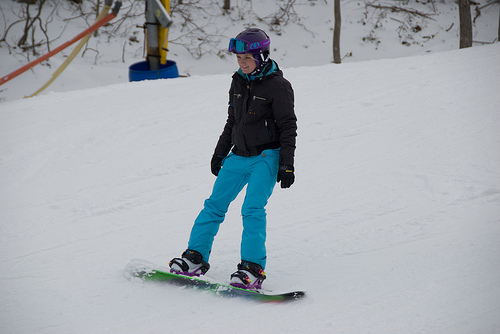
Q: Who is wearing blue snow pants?
A: A girl.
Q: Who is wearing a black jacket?
A: A girl.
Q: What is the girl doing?
A: Snowboarding.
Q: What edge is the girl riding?
A: Heelside.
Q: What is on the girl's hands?
A: Gloves.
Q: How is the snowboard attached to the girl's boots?
A: Bindings.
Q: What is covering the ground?
A: Snow.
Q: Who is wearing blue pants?
A: The girl.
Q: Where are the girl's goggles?
A: Around her helmet.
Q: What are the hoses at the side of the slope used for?
A: Snowmaking.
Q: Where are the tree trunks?
A: On the side of the slope.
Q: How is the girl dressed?
A: In heavy coat.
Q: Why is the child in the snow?
A: She is snow boarding.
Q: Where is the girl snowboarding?
A: Mountain.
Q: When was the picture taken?
A: Winter.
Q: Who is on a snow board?
A: Girl.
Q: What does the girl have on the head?
A: Helmet.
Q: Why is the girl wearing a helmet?
A: Safety.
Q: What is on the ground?
A: Snow.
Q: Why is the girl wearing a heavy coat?
A: Keep warm.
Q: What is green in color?
A: Snowboard.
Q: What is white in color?
A: Snow.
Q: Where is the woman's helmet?
A: On her head.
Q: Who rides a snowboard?
A: Snowboarders.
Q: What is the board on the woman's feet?
A: Snowboard.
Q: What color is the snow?
A: White.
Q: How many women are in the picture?
A: One.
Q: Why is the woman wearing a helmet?
A: Safety.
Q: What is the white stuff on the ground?
A: Snow.